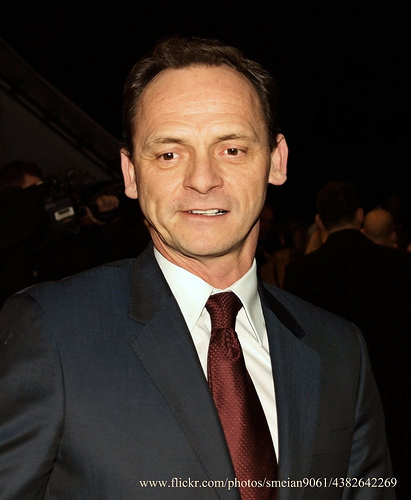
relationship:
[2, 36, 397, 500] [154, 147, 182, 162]
man has eye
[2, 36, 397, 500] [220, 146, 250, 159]
man has eye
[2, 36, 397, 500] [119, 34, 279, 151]
man has hair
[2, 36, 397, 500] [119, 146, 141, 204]
man has ear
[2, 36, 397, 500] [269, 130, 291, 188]
man has ear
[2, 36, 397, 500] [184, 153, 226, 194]
man has nose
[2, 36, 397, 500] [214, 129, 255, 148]
man has eyebrow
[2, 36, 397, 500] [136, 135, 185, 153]
man has eyebrow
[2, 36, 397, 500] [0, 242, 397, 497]
man wears jacket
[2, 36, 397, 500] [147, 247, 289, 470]
man wears shirt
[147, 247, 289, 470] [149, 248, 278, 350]
shirt has collar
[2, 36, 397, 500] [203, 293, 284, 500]
man wears necktie